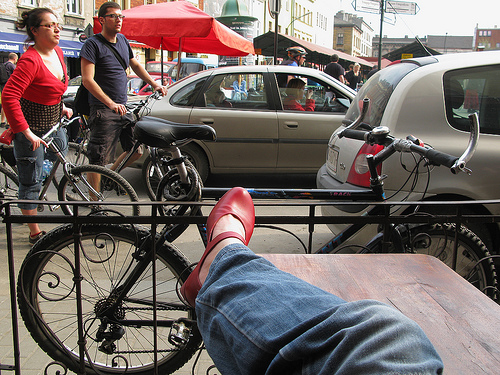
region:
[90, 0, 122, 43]
the head of a man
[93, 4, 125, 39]
the face of a man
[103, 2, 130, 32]
the eyes of a man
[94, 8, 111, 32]
the ear of a man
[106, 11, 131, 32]
the nose of a man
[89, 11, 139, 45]
the lips of a man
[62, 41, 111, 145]
the arm of a man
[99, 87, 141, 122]
the hand of a man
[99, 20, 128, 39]
the neck of a man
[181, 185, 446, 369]
A human leg on the bench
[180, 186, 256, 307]
Red shoe on the foot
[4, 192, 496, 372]
Metal fence on the road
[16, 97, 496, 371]
Bike locked to the metal fence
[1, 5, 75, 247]
Woman riding a bike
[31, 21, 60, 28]
Glasses on the woman's face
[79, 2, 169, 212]
Man riding a bike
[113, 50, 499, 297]
Cars on the street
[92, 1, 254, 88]
Red umbrella on the street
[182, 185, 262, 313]
red shoe on foot of woman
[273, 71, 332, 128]
woman driving car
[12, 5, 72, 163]
woman in red blouse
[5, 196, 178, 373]
black metal guard railing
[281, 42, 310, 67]
man wearing safety helmet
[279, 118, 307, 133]
door handle on side of car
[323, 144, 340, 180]
license plate on back of vehicle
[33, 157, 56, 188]
plastic water bottle on bike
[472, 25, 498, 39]
row of windows on side of building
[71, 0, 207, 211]
a man standing over a bike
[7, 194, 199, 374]
a wrought iron fence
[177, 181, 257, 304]
a red leather shoe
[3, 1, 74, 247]
a woman standing on the sidewalk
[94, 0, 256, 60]
a red fabric canopy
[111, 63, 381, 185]
a small tan sedan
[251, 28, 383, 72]
a large black canopy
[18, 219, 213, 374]
bicycle tire with thick tread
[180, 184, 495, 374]
leg on a wood table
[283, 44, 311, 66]
a man wearing a helmet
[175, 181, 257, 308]
red shoe resting on table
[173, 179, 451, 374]
woman's leg resting on table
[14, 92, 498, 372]
black bicycle chained to fence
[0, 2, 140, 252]
girl in red shirt standing with bicycle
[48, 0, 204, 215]
man wearing blue shirt standing with bicycle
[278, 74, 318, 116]
woman in red shirt sitting in car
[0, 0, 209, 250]
two people standing in street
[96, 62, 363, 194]
beige car sitting in street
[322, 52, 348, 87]
man in black shirt standing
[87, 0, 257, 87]
large red umbrella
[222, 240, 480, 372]
Thee wooden table near the fence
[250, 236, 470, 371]
A wooden table near the fence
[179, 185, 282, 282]
The red shoe on the woman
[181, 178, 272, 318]
A red ladies shoe.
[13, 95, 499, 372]
A older bike leaning up agains the fence.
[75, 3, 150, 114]
A man with a blue shirt on.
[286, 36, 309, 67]
A person with a bike helmet on behind the car.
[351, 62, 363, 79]
A man with a white beard.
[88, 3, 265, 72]
An open red square umbrella.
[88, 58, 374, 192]
A tan car with a person in it.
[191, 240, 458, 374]
A leg with bluejeans on it.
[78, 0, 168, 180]
man on a bike on the road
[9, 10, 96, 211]
man on a bike on the road